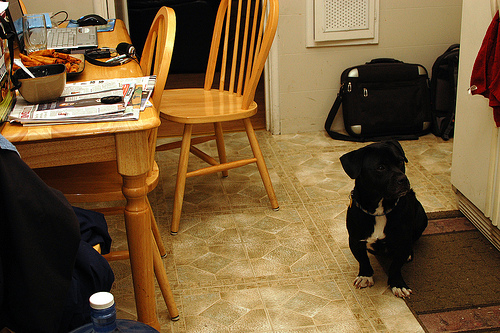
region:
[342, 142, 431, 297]
a black dog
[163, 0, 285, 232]
a wooden chair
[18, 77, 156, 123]
magazines on a table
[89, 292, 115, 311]
top of a water bottle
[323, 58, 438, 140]
a black bag on the floor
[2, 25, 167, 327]
a wooden table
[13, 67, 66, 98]
a brown bowl on the table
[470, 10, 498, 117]
a red clothing hanged on the wall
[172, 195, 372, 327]
tiles on the floor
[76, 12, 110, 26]
an electronic mouse on the table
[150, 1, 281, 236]
A brown chair with four legs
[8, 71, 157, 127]
A news paper on the table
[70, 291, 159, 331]
A blue water Jud sitting on the floor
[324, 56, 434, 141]
black and gold carrying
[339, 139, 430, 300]
A black and white dog sitting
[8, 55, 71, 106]
A brown bowl on the table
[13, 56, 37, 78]
A silver spoon in the bowl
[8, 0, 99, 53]
A gray laptop on the table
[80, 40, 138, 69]
black and gray head phones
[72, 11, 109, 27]
A computer mouse on table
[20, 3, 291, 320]
table and chairs made of wood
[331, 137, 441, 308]
a black dog sitting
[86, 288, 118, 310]
a white lid to water jug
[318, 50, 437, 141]
a laptop carrying case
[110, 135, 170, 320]
wood leg of a table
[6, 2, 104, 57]
a laptop sitting on the table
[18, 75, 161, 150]
a pile of newspapers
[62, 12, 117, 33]
a black mouse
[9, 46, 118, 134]
a bowl sitting on top of newspaper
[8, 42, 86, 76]
a plate of food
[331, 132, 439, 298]
a dog sitting on a carpet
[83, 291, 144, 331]
water jug with a white lid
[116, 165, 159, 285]
a wooden table leg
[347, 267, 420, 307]
a dog with white paws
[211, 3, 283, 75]
a wooden chair back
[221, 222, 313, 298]
brown linoleum floor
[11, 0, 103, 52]
a silver laptop on a table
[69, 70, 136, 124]
newspaper on a table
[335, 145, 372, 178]
a dog's ear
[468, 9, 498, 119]
a red dish towel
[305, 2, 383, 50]
a white heating vent in the wall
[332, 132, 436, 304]
a black and white dog sitting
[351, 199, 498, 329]
a brown mat on the floor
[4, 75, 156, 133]
stack of magazines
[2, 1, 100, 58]
a silver laptop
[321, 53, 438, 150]
black and silver laptop bag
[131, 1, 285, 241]
two wooden chairs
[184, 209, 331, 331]
brown tile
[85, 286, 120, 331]
clear blue bottle with white lid